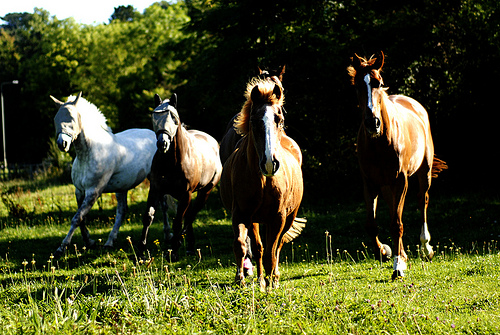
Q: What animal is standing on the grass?
A: Horses.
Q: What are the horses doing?
A: Walking.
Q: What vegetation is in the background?
A: Green trees.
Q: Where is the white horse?
A: On the far left.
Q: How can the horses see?
A: The fly mask is mesh and does not obstruct vision.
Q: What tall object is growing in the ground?
A: Weeds.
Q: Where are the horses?
A: In a field.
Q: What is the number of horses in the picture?
A: 5.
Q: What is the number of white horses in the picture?
A: 1.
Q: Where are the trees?
A: Behind the horses.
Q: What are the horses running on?
A: Grass.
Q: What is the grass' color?
A: Green.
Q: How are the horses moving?
A: Running.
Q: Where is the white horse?
A: On the left.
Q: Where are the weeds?
A: In the grass.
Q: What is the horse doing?
A: Running.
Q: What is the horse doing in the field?
A: Running.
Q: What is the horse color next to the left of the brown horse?
A: White.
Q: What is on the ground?
A: Grass.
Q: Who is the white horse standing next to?
A: Brown horse.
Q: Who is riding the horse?
A: No person.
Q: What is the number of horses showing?
A: Four.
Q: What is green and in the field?
A: Grass.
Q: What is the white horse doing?
A: Running.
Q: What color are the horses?
A: Brown and white.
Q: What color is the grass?
A: Green.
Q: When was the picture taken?
A: Daytime.